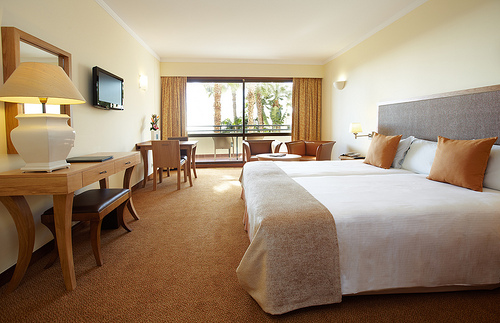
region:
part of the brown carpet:
[161, 199, 227, 305]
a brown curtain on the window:
[295, 77, 321, 139]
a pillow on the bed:
[434, 136, 487, 187]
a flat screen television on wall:
[96, 64, 131, 108]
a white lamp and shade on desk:
[2, 55, 79, 170]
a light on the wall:
[326, 75, 355, 90]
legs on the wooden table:
[0, 174, 75, 293]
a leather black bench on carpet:
[67, 183, 143, 259]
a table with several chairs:
[142, 139, 204, 188]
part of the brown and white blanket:
[245, 163, 441, 279]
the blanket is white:
[368, 181, 428, 227]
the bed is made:
[329, 166, 487, 228]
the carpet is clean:
[143, 233, 206, 294]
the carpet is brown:
[166, 256, 210, 292]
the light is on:
[20, 81, 70, 113]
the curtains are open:
[288, 80, 327, 134]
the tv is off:
[97, 70, 124, 105]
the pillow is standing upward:
[373, 138, 388, 163]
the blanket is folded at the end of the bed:
[279, 221, 318, 267]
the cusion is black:
[85, 190, 102, 207]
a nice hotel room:
[16, 18, 486, 318]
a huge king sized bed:
[236, 85, 496, 311]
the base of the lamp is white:
[0, 105, 93, 181]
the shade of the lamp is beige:
[0, 56, 80, 121]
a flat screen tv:
[90, 60, 133, 115]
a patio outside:
[183, 79, 293, 169]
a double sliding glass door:
[188, 88, 290, 158]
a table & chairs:
[143, 130, 205, 183]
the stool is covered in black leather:
[42, 179, 138, 260]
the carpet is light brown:
[156, 203, 228, 306]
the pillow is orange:
[356, 123, 400, 172]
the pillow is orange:
[418, 109, 491, 212]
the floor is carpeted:
[146, 228, 186, 292]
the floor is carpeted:
[191, 241, 253, 308]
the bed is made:
[261, 103, 465, 315]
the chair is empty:
[213, 78, 323, 168]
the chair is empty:
[156, 124, 193, 181]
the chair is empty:
[285, 112, 337, 181]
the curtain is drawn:
[161, 60, 253, 187]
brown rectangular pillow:
[365, 131, 399, 168]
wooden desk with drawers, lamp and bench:
[1, 27, 141, 288]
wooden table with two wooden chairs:
[136, 137, 200, 187]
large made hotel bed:
[244, 80, 490, 314]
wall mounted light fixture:
[334, 71, 347, 88]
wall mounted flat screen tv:
[88, 65, 122, 110]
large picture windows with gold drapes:
[162, 76, 319, 159]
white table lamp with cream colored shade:
[0, 62, 86, 171]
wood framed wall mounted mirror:
[2, 27, 74, 153]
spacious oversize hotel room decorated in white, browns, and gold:
[3, 1, 497, 321]